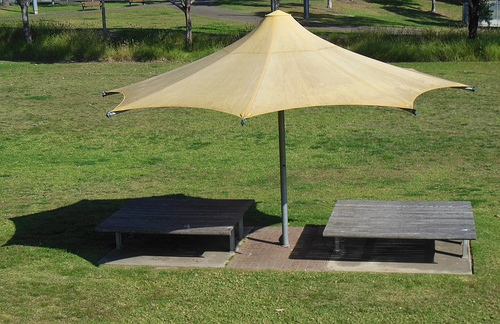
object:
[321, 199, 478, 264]
platform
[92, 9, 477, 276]
patio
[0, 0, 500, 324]
park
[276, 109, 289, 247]
pole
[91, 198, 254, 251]
platforms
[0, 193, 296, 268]
shadow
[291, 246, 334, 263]
bricks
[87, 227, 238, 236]
strip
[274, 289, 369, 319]
leaf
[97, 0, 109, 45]
tree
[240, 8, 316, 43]
top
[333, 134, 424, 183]
grass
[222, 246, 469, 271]
ground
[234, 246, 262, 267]
bricks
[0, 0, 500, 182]
field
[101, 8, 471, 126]
umbrella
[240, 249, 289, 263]
concrete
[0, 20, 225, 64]
grass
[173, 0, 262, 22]
road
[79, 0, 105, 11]
bench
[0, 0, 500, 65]
background